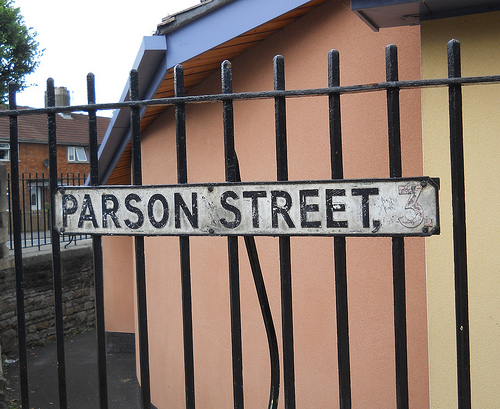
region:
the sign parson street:
[46, 178, 437, 238]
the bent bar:
[225, 150, 282, 405]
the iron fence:
[0, 36, 498, 406]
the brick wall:
[0, 246, 95, 362]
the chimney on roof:
[42, 81, 73, 112]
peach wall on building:
[82, 7, 424, 405]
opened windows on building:
[1, 140, 88, 165]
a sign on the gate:
[58, 188, 425, 236]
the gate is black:
[233, 293, 323, 369]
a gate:
[231, 284, 321, 376]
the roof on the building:
[25, 116, 45, 133]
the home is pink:
[237, 108, 258, 156]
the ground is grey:
[66, 353, 91, 393]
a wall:
[27, 282, 50, 327]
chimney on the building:
[52, 82, 67, 104]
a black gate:
[134, 89, 339, 141]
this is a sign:
[29, 115, 469, 283]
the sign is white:
[31, 162, 496, 236]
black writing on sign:
[32, 165, 481, 268]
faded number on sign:
[376, 159, 441, 240]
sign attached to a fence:
[12, 54, 489, 400]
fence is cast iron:
[0, 27, 499, 403]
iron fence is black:
[5, 40, 498, 406]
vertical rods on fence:
[8, 12, 498, 390]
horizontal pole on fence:
[9, 65, 499, 120]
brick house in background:
[4, 41, 155, 278]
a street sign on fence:
[37, 155, 463, 304]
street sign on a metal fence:
[22, 130, 496, 347]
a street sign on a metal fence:
[32, 132, 447, 299]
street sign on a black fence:
[24, 126, 459, 321]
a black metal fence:
[200, 124, 465, 312]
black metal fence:
[317, 292, 479, 315]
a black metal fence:
[292, 238, 496, 406]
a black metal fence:
[15, 121, 315, 406]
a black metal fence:
[104, 43, 374, 229]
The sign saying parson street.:
[53, 177, 449, 254]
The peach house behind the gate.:
[87, 120, 427, 403]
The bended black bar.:
[216, 147, 287, 398]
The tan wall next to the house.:
[416, 120, 498, 397]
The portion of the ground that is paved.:
[24, 323, 150, 407]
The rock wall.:
[6, 276, 103, 401]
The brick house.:
[4, 125, 98, 254]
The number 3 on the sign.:
[393, 162, 462, 248]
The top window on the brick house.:
[63, 147, 94, 171]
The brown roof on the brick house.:
[2, 120, 112, 146]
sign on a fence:
[21, 30, 488, 403]